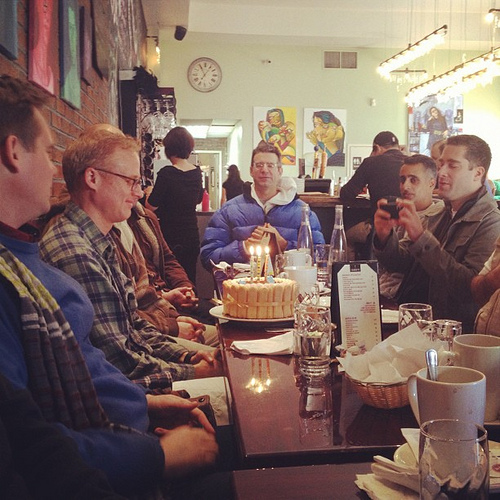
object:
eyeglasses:
[251, 161, 282, 169]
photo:
[0, 0, 495, 497]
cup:
[294, 307, 333, 367]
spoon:
[425, 348, 438, 381]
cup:
[406, 365, 487, 479]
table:
[215, 258, 487, 454]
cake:
[222, 277, 296, 319]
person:
[370, 134, 500, 326]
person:
[370, 154, 446, 299]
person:
[199, 143, 332, 271]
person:
[129, 197, 222, 325]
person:
[39, 124, 221, 377]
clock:
[187, 57, 222, 93]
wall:
[143, 30, 404, 182]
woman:
[144, 126, 205, 294]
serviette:
[230, 330, 302, 356]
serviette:
[351, 426, 499, 498]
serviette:
[209, 258, 251, 278]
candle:
[264, 246, 274, 276]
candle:
[256, 246, 262, 283]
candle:
[249, 245, 255, 282]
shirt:
[39, 201, 199, 382]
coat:
[198, 176, 326, 274]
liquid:
[299, 333, 332, 372]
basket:
[345, 370, 414, 406]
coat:
[373, 189, 500, 328]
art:
[253, 107, 297, 165]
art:
[303, 108, 347, 180]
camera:
[380, 196, 403, 219]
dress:
[147, 165, 206, 267]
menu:
[329, 260, 384, 359]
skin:
[99, 156, 128, 213]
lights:
[481, 12, 499, 30]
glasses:
[162, 98, 175, 124]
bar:
[136, 86, 176, 187]